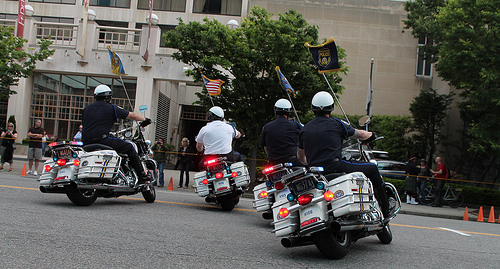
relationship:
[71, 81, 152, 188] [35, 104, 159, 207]
policeman on motorcycle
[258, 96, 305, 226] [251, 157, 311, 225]
policeman on motorcycle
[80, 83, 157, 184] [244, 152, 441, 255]
policeman on motorcycle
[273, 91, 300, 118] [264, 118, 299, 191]
helmet on policeman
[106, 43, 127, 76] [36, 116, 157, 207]
flag on motorcycle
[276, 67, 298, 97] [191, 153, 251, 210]
flag on motorcycle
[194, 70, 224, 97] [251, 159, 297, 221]
flag on motorcycle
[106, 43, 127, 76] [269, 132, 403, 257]
flag on motorcycle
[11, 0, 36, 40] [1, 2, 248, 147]
flag on white building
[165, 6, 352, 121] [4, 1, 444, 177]
bush in front of building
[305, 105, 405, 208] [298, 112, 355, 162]
police officer wearing shirt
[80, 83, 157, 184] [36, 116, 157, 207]
policeman riding motorcycle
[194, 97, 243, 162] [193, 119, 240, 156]
policeman wearing shirt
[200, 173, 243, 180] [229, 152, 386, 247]
brakelights on motorcycles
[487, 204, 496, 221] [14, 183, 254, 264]
cone by road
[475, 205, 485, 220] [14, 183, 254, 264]
cone by road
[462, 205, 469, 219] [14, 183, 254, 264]
cone by road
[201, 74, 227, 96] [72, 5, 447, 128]
flag in front of building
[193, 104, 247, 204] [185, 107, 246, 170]
man wearing shirt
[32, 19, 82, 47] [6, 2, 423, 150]
railing on building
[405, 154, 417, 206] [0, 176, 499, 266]
person standing road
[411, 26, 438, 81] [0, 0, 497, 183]
window in building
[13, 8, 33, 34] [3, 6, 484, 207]
sign on building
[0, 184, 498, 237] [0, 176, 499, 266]
yellow line on road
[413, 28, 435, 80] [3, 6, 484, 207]
window on building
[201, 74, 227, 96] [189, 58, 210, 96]
flag on pole